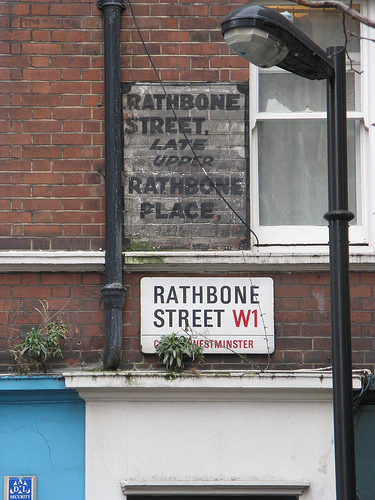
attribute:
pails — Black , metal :
[221, 2, 323, 70]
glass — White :
[222, 30, 291, 73]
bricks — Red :
[18, 0, 86, 248]